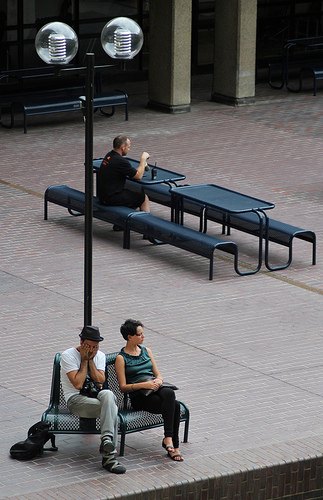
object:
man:
[58, 321, 126, 475]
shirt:
[59, 346, 105, 402]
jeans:
[65, 388, 119, 456]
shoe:
[98, 438, 116, 458]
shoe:
[102, 455, 127, 473]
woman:
[115, 319, 182, 462]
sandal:
[167, 453, 184, 464]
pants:
[130, 386, 180, 446]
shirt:
[119, 346, 154, 385]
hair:
[119, 318, 144, 340]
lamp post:
[34, 17, 144, 328]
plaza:
[0, 1, 322, 498]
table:
[169, 183, 275, 280]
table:
[85, 156, 187, 226]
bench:
[126, 209, 239, 282]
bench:
[44, 183, 149, 250]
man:
[96, 134, 150, 213]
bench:
[42, 352, 190, 455]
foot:
[162, 439, 176, 454]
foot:
[170, 447, 184, 462]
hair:
[111, 133, 127, 148]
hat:
[79, 325, 104, 343]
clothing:
[96, 151, 146, 209]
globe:
[33, 21, 80, 64]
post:
[83, 53, 94, 326]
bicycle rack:
[265, 40, 321, 95]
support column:
[209, 0, 257, 105]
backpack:
[9, 418, 59, 461]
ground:
[0, 68, 322, 499]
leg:
[98, 388, 119, 453]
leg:
[67, 395, 101, 417]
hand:
[78, 342, 90, 358]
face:
[81, 339, 98, 360]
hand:
[89, 347, 97, 362]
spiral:
[113, 29, 132, 56]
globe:
[100, 16, 144, 62]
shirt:
[97, 151, 138, 197]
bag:
[136, 380, 178, 397]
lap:
[130, 385, 174, 410]